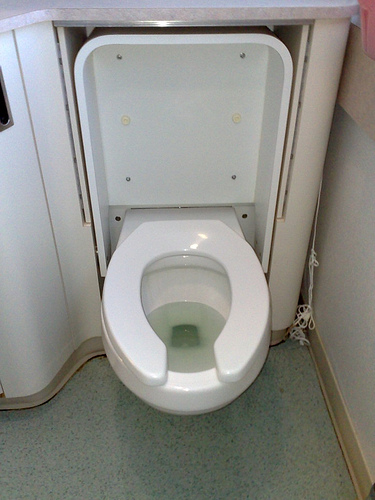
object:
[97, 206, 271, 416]
toilet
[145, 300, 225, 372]
water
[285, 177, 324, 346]
cord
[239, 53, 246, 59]
bolt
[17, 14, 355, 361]
wall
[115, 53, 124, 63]
bolt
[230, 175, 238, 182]
bolt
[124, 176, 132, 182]
bolt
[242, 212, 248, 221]
bolt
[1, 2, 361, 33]
countertop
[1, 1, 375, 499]
bathroom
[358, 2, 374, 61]
container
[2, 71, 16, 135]
hole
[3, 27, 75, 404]
cabinet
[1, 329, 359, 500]
floor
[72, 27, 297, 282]
toilet structure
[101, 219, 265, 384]
toilet seat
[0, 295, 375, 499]
molding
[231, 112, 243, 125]
screw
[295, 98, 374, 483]
wall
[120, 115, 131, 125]
screw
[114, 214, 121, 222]
bolt